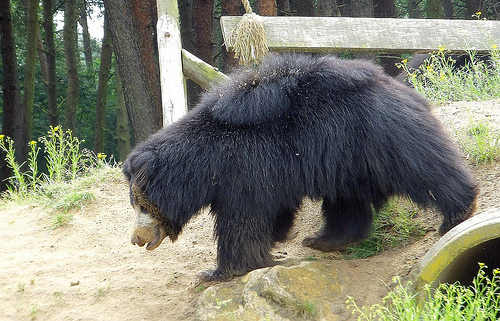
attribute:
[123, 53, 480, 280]
bear — walking, black, furry, small, shaggy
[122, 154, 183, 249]
face — brown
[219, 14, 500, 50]
board — wooden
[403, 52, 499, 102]
weeds — green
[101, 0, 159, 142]
trunks — brown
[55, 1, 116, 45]
sky — white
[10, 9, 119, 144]
trees — green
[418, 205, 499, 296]
tunnel — small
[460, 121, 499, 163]
shrubs — green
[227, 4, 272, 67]
rope — frayed, hanging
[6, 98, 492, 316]
path — sand, dirt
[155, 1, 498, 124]
fence — broken, wood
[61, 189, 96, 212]
patch — small 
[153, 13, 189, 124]
plank — white-washed